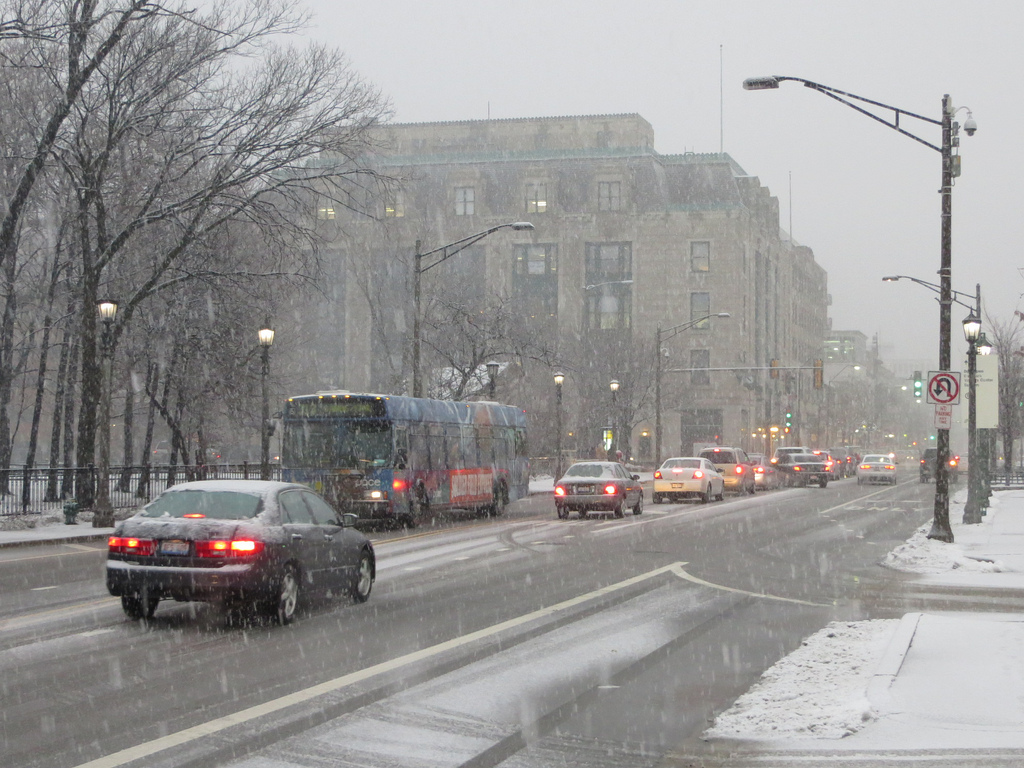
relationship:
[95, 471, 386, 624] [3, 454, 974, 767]
traffic on street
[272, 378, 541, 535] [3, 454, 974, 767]
traffic in street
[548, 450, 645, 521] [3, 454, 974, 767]
traffic in street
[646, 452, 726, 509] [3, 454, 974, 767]
traffic in street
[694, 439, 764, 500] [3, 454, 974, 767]
traffic in street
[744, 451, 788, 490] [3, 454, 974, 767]
traffic in street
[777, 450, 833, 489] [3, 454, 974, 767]
traffic in street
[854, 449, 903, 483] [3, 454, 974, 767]
traffic in street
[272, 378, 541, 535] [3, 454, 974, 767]
traffic on street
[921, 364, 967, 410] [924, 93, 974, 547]
sign on post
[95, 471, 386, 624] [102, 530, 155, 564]
traffic has lights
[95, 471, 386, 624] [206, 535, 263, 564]
traffic has lights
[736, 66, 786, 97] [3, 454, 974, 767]
lamps along street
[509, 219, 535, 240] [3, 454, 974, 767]
lamps along street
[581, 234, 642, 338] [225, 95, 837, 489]
windows on building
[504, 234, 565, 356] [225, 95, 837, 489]
windows on building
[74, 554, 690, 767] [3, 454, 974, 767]
line on street